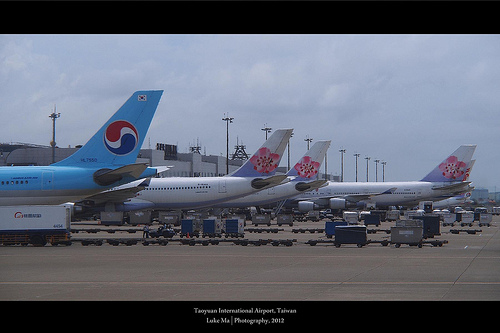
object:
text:
[194, 308, 296, 325]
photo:
[0, 33, 498, 301]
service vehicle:
[1, 205, 72, 246]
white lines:
[464, 245, 468, 248]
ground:
[2, 208, 497, 299]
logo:
[103, 120, 139, 156]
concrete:
[0, 247, 500, 301]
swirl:
[103, 120, 139, 156]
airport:
[0, 34, 500, 301]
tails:
[454, 159, 475, 207]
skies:
[1, 35, 498, 192]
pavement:
[0, 246, 499, 298]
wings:
[96, 162, 151, 181]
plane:
[391, 159, 476, 210]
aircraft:
[61, 128, 294, 227]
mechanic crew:
[142, 223, 149, 239]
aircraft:
[263, 144, 478, 222]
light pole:
[383, 164, 385, 182]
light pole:
[376, 162, 378, 182]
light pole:
[356, 156, 358, 181]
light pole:
[340, 152, 344, 182]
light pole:
[366, 159, 368, 181]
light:
[222, 112, 234, 174]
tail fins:
[223, 128, 294, 177]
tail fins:
[285, 140, 332, 181]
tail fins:
[419, 145, 476, 181]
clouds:
[0, 34, 500, 189]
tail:
[47, 90, 175, 203]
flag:
[138, 94, 146, 101]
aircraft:
[0, 90, 174, 247]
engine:
[297, 200, 324, 211]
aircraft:
[212, 140, 330, 227]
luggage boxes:
[334, 225, 367, 243]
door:
[219, 181, 225, 193]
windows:
[144, 186, 211, 191]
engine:
[86, 198, 156, 213]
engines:
[329, 197, 357, 209]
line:
[0, 281, 500, 285]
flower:
[250, 147, 280, 175]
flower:
[295, 156, 321, 179]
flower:
[439, 156, 466, 180]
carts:
[179, 219, 246, 238]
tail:
[223, 128, 299, 201]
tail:
[284, 140, 329, 198]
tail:
[419, 145, 475, 204]